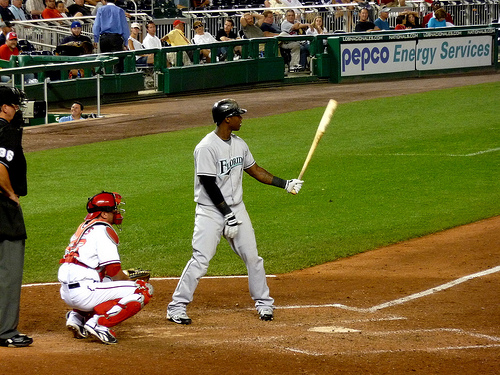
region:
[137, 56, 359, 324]
baseball batter on home base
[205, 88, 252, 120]
black baseball cap on batter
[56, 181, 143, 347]
catcher crouching to catch the ball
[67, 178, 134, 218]
red catchers helmet for protection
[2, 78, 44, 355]
umpire behind the baseball catcher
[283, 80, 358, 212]
wooden baseball bat to hit the ball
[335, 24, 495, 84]
pepco energy services advertising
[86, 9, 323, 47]
baseball fans watching the game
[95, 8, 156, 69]
man in a blue dress shirt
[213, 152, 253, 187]
florida marlins baseball logo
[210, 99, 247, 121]
a dark baseball helmet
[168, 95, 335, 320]
a baseball player holding a bat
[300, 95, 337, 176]
a wooden baseball bat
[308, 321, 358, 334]
home plate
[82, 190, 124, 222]
a red catcher's mask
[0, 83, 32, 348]
baseball umpire in black hat and shirt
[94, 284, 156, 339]
red baseball knee guards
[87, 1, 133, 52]
man in crowd wearing a blue long sleeve shirt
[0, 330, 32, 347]
a pair of black shoes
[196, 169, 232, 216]
a black arm sleeve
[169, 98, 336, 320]
a baseball player with bat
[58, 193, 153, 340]
a baseball catcher squating down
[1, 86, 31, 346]
a baseball umpire in black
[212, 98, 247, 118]
a black baseball helmet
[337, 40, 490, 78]
an advertisement banner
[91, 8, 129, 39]
blue long sleeve shirt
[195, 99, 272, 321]
A Florida baseball player at bat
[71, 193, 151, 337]
a baseball catcher in red and white uniform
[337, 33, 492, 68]
a stadium barrier advertising banner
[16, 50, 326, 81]
a low green stadium barrier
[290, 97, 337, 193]
a baseball bat being held one-handed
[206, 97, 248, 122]
a hard black helmet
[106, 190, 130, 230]
a red catcher's mask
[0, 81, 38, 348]
an umpire calling pitches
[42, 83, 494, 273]
short bright green stadium grass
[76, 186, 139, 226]
black and red umpire's helmet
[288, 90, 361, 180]
wooden baseball bat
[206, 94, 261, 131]
black and white baseball helmet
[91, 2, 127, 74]
man in blue shirt and black pants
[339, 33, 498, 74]
large blue and white advertisement sign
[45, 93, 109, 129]
man with black hair sitting in dugout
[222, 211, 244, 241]
black and white baseball glove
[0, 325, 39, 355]
black and white dress shoes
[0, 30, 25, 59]
man in red hat and shirt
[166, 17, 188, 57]
man in yellow shirt and red hat